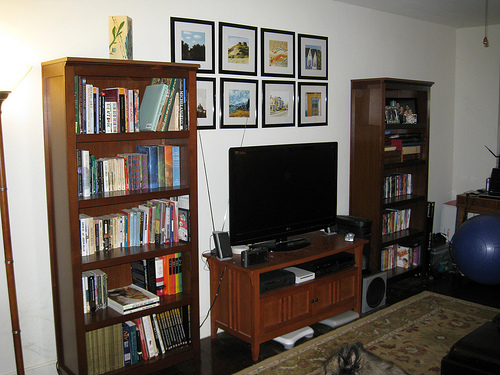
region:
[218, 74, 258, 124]
picture hanging on wall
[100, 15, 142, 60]
box on top of bookshelf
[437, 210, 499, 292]
large blue ball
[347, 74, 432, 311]
bookshelf full of videos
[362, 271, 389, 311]
stereo speaker on floor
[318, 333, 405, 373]
dog on floor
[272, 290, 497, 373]
rug on floor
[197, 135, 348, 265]
tv on top of stereo cabinet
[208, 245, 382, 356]
stereo cabinet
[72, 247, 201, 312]
cd music and books and videos on bookshelf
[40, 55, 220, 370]
A bookshelf full of books.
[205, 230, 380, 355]
A TV stand.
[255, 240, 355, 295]
Electronic entertainment devices.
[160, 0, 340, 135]
Two rows of pictures.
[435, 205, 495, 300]
A blue exercise ball.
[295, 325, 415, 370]
The fur of an animal.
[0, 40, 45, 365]
A lamp.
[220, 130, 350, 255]
A flat screen tv.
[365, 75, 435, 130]
Family photos on the top shelf.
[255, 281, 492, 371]
A large rug is on the ground.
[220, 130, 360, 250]
A flat screen TV.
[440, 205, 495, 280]
Blue ball in the room.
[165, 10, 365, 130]
Two rows of photographs.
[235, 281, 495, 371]
A rug on the floor.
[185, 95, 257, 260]
A pair of television rabbit ears.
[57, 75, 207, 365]
Books on the shelves.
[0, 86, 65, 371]
A lamp next to the wall.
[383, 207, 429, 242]
A shelf with books on it.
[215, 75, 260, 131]
A picture in a black frame.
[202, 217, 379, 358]
A brown television console.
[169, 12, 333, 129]
eight small pictures on wall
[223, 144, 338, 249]
flat screen TV on shelf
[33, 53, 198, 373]
brown tall bookshelf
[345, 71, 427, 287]
brown tall movie shelf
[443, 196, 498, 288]
blue exercise ball on floor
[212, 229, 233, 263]
black and silver speaker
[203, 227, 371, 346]
wooden brown tv shelf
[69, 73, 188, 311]
books on wooden shelf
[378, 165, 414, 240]
movies on wooden shelf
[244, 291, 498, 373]
tan rug with pattern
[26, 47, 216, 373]
A brown set of bookshelves.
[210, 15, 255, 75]
A picture on the wall.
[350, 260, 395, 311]
A speaker on the floor.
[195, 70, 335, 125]
A row of pictures.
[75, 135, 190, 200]
Books on a shelf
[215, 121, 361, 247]
A flatscreen television set.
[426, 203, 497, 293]
A large blue ball.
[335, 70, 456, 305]
Another set of bookshelves.